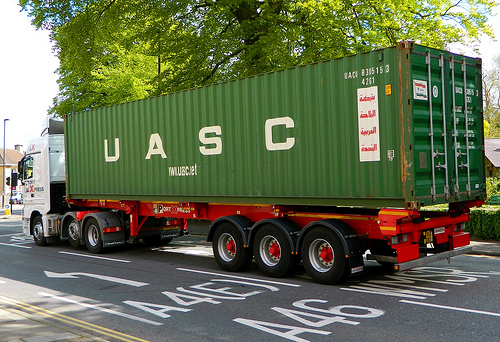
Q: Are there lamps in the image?
A: Yes, there is a lamp.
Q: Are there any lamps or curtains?
A: Yes, there is a lamp.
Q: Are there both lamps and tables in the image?
A: No, there is a lamp but no tables.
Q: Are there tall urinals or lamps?
A: Yes, there is a tall lamp.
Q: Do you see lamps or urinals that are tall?
A: Yes, the lamp is tall.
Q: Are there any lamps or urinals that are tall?
A: Yes, the lamp is tall.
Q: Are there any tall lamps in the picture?
A: Yes, there is a tall lamp.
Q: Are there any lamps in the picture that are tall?
A: Yes, there is a lamp that is tall.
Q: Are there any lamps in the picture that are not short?
A: Yes, there is a tall lamp.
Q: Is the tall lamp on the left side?
A: Yes, the lamp is on the left of the image.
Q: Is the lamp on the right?
A: No, the lamp is on the left of the image.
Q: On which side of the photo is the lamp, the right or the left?
A: The lamp is on the left of the image.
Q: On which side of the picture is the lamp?
A: The lamp is on the left of the image.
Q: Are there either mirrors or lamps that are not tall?
A: No, there is a lamp but it is tall.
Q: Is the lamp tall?
A: Yes, the lamp is tall.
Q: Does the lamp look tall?
A: Yes, the lamp is tall.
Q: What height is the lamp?
A: The lamp is tall.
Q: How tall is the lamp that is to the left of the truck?
A: The lamp is tall.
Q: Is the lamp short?
A: No, the lamp is tall.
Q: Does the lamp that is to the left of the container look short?
A: No, the lamp is tall.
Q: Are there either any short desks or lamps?
A: No, there is a lamp but it is tall.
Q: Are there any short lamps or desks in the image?
A: No, there is a lamp but it is tall.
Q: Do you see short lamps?
A: No, there is a lamp but it is tall.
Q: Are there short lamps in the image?
A: No, there is a lamp but it is tall.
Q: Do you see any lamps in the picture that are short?
A: No, there is a lamp but it is tall.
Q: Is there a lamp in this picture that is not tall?
A: No, there is a lamp but it is tall.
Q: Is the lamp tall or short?
A: The lamp is tall.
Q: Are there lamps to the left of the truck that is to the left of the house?
A: Yes, there is a lamp to the left of the truck.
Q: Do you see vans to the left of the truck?
A: No, there is a lamp to the left of the truck.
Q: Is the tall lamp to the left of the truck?
A: Yes, the lamp is to the left of the truck.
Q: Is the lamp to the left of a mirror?
A: No, the lamp is to the left of the truck.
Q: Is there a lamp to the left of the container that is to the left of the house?
A: Yes, there is a lamp to the left of the container.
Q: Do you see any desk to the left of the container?
A: No, there is a lamp to the left of the container.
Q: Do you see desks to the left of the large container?
A: No, there is a lamp to the left of the container.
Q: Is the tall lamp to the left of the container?
A: Yes, the lamp is to the left of the container.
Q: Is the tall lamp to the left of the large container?
A: Yes, the lamp is to the left of the container.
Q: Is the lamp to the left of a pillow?
A: No, the lamp is to the left of the container.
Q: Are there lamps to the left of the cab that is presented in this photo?
A: Yes, there is a lamp to the left of the cab.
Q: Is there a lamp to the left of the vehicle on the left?
A: Yes, there is a lamp to the left of the cab.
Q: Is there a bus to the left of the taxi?
A: No, there is a lamp to the left of the taxi.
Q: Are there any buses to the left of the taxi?
A: No, there is a lamp to the left of the taxi.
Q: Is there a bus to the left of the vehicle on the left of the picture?
A: No, there is a lamp to the left of the taxi.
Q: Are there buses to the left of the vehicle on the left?
A: No, there is a lamp to the left of the taxi.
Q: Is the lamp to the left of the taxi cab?
A: Yes, the lamp is to the left of the taxi cab.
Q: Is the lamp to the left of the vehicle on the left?
A: Yes, the lamp is to the left of the taxi cab.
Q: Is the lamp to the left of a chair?
A: No, the lamp is to the left of the taxi cab.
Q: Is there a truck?
A: Yes, there is a truck.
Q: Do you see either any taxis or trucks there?
A: Yes, there is a truck.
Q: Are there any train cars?
A: No, there are no train cars.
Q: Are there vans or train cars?
A: No, there are no train cars or vans.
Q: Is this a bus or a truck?
A: This is a truck.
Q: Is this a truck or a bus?
A: This is a truck.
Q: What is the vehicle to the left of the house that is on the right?
A: The vehicle is a truck.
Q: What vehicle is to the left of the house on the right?
A: The vehicle is a truck.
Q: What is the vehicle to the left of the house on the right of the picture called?
A: The vehicle is a truck.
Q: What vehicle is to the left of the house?
A: The vehicle is a truck.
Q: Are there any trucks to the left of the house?
A: Yes, there is a truck to the left of the house.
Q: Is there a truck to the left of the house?
A: Yes, there is a truck to the left of the house.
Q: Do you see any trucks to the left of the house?
A: Yes, there is a truck to the left of the house.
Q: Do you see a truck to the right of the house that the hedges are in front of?
A: No, the truck is to the left of the house.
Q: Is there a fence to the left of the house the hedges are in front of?
A: No, there is a truck to the left of the house.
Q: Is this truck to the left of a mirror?
A: No, the truck is to the left of a house.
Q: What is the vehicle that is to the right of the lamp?
A: The vehicle is a truck.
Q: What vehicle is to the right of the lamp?
A: The vehicle is a truck.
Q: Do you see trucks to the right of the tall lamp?
A: Yes, there is a truck to the right of the lamp.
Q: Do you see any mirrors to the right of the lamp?
A: No, there is a truck to the right of the lamp.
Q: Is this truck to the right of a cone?
A: No, the truck is to the right of the lamp.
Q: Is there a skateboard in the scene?
A: No, there are no skateboards.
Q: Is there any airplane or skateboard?
A: No, there are no skateboards or airplanes.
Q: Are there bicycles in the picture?
A: No, there are no bicycles.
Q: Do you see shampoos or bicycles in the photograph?
A: No, there are no bicycles or shampoos.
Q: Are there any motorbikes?
A: No, there are no motorbikes.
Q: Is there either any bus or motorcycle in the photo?
A: No, there are no motorcycles or buses.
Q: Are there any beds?
A: Yes, there is a bed.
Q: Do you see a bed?
A: Yes, there is a bed.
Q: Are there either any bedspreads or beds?
A: Yes, there is a bed.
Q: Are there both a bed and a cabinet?
A: No, there is a bed but no cabinets.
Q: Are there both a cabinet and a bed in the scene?
A: No, there is a bed but no cabinets.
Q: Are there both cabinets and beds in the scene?
A: No, there is a bed but no cabinets.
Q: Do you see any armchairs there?
A: No, there are no armchairs.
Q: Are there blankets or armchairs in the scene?
A: No, there are no armchairs or blankets.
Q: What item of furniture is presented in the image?
A: The piece of furniture is a bed.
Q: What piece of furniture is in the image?
A: The piece of furniture is a bed.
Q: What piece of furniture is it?
A: The piece of furniture is a bed.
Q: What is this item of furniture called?
A: That is a bed.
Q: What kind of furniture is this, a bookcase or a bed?
A: That is a bed.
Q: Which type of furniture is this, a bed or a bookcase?
A: That is a bed.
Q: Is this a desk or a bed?
A: This is a bed.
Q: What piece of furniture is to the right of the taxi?
A: The piece of furniture is a bed.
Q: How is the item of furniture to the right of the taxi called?
A: The piece of furniture is a bed.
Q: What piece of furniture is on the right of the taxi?
A: The piece of furniture is a bed.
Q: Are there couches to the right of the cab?
A: No, there is a bed to the right of the cab.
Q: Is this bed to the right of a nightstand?
A: No, the bed is to the right of the cab.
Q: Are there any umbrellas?
A: No, there are no umbrellas.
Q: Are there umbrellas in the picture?
A: No, there are no umbrellas.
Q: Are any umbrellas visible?
A: No, there are no umbrellas.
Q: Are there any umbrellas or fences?
A: No, there are no umbrellas or fences.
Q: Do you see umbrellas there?
A: No, there are no umbrellas.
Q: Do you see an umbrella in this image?
A: No, there are no umbrellas.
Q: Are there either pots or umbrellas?
A: No, there are no umbrellas or pots.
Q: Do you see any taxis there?
A: Yes, there is a taxi.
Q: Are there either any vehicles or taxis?
A: Yes, there is a taxi.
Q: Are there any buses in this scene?
A: No, there are no buses.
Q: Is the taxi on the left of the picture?
A: Yes, the taxi is on the left of the image.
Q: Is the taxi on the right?
A: No, the taxi is on the left of the image.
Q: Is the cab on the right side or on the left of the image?
A: The cab is on the left of the image.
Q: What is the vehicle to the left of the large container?
A: The vehicle is a taxi.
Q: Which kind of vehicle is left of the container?
A: The vehicle is a taxi.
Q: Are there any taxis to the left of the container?
A: Yes, there is a taxi to the left of the container.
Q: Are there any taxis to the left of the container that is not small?
A: Yes, there is a taxi to the left of the container.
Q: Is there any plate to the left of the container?
A: No, there is a taxi to the left of the container.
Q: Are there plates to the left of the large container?
A: No, there is a taxi to the left of the container.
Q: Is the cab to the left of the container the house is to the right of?
A: Yes, the cab is to the left of the container.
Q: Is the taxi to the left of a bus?
A: No, the taxi is to the left of the container.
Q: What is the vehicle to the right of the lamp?
A: The vehicle is a taxi.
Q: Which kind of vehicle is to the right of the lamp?
A: The vehicle is a taxi.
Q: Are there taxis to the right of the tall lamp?
A: Yes, there is a taxi to the right of the lamp.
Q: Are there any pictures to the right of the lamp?
A: No, there is a taxi to the right of the lamp.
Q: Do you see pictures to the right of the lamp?
A: No, there is a taxi to the right of the lamp.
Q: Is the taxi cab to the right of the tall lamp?
A: Yes, the taxi cab is to the right of the lamp.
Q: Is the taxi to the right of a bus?
A: No, the taxi is to the right of the lamp.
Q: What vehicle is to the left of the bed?
A: The vehicle is a taxi.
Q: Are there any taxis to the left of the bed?
A: Yes, there is a taxi to the left of the bed.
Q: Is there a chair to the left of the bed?
A: No, there is a taxi to the left of the bed.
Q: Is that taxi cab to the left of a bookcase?
A: No, the taxi cab is to the left of a bed.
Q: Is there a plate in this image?
A: No, there are no plates.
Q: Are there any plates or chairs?
A: No, there are no plates or chairs.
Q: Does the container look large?
A: Yes, the container is large.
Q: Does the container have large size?
A: Yes, the container is large.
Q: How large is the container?
A: The container is large.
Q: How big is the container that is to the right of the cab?
A: The container is large.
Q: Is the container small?
A: No, the container is large.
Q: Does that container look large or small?
A: The container is large.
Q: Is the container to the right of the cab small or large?
A: The container is large.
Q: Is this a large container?
A: Yes, this is a large container.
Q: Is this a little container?
A: No, this is a large container.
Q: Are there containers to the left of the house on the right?
A: Yes, there is a container to the left of the house.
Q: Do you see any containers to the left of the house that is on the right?
A: Yes, there is a container to the left of the house.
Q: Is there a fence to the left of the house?
A: No, there is a container to the left of the house.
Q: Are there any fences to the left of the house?
A: No, there is a container to the left of the house.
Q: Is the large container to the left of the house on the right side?
A: Yes, the container is to the left of the house.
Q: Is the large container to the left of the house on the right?
A: Yes, the container is to the left of the house.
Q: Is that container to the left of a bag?
A: No, the container is to the left of the house.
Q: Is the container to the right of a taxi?
A: Yes, the container is to the right of a taxi.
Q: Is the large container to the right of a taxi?
A: Yes, the container is to the right of a taxi.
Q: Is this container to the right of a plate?
A: No, the container is to the right of a taxi.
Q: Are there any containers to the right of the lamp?
A: Yes, there is a container to the right of the lamp.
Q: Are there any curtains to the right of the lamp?
A: No, there is a container to the right of the lamp.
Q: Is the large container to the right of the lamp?
A: Yes, the container is to the right of the lamp.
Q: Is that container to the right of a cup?
A: No, the container is to the right of the lamp.